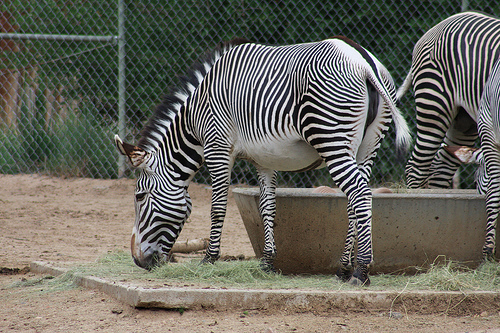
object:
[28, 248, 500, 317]
platform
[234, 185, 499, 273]
gray tub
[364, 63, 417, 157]
tail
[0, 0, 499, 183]
fence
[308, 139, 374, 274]
legs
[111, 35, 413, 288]
zebra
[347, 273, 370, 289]
hooves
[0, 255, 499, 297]
grass